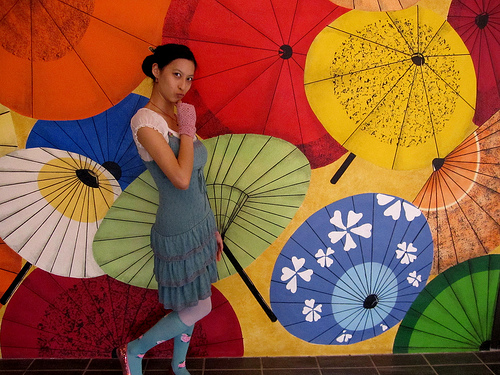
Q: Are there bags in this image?
A: No, there are no bags.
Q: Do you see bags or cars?
A: No, there are no bags or cars.